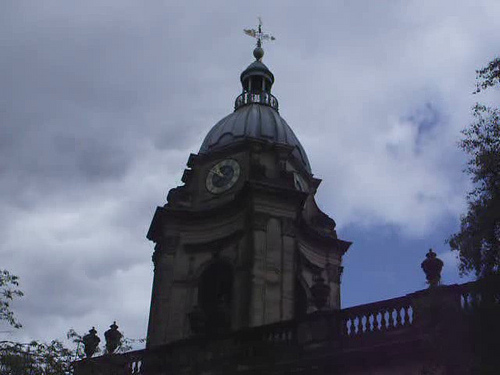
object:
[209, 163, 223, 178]
two needles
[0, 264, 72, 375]
leaves/branches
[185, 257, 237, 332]
design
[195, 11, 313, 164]
top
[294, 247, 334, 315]
design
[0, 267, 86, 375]
trees leaves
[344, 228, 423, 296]
blue sky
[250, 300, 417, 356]
decorative holes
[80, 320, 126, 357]
two decorations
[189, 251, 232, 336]
bell chamber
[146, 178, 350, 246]
fancy woodwork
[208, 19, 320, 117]
dome top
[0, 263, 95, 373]
tree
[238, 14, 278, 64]
weather vane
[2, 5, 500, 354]
cloudy sky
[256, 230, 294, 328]
stone work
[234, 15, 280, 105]
church steeple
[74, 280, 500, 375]
cement railing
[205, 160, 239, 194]
white area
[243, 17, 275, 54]
cross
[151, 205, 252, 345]
section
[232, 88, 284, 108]
stand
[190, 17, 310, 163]
dome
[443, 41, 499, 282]
tree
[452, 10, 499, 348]
side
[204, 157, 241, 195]
clock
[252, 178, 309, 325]
design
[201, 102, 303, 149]
designs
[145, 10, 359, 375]
building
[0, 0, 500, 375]
clouds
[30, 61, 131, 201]
mysterious shapes